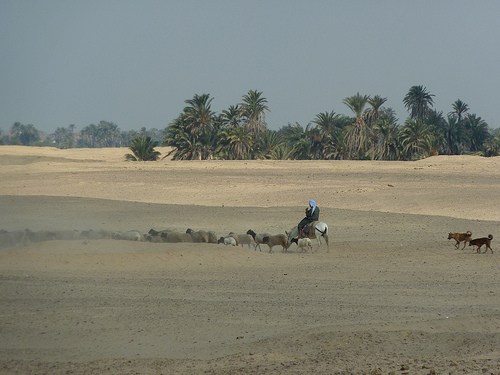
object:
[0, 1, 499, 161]
background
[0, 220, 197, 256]
dust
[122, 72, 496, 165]
cluster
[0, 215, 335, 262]
herd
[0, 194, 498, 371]
oasis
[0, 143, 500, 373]
desert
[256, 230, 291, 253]
sheep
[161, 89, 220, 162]
palm trees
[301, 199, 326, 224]
man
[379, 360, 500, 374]
stones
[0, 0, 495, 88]
sky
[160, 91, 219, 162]
leaves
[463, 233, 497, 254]
dogs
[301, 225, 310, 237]
pack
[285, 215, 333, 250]
donkey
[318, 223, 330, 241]
tail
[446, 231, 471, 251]
dog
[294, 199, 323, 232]
person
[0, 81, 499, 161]
line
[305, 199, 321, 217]
headscarf